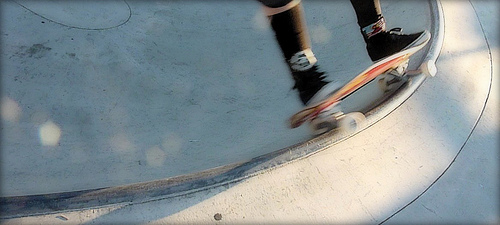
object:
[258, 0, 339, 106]
legs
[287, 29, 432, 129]
skateboard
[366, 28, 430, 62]
sneaker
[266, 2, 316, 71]
sock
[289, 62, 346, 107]
shoe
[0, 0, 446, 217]
ramp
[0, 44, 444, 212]
edge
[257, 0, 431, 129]
skateboarder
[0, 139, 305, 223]
shadow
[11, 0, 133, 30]
pattern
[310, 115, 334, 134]
wheel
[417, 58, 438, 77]
wheel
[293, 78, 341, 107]
foot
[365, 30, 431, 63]
foot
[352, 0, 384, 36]
sock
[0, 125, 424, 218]
rail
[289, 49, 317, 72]
detail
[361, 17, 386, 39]
detail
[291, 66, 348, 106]
sneakers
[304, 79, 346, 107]
sole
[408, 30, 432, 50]
sole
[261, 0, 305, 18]
skin